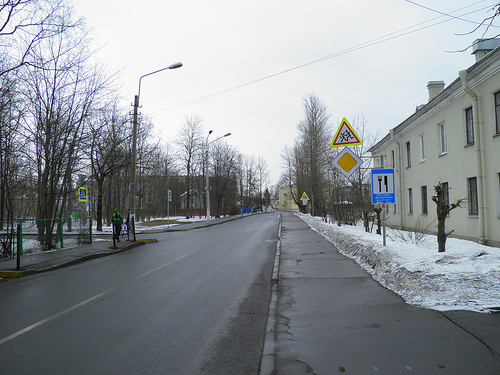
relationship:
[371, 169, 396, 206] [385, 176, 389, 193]
sign has knife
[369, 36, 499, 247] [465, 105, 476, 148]
building has window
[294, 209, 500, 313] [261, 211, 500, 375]
snow on pavement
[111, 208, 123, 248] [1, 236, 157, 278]
person on sidewalk